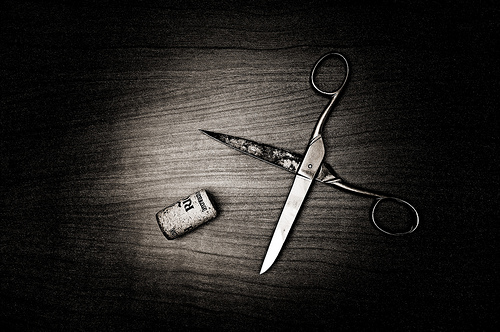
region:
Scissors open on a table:
[192, 53, 421, 270]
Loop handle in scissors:
[372, 193, 419, 238]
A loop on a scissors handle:
[307, 51, 355, 96]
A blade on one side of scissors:
[252, 177, 321, 271]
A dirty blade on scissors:
[197, 126, 297, 176]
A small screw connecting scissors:
[305, 162, 312, 169]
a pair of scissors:
[165, 39, 455, 287]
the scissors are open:
[189, 49, 431, 283]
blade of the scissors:
[239, 160, 334, 307]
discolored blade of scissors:
[195, 118, 290, 180]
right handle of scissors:
[297, 30, 365, 110]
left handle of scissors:
[350, 168, 422, 260]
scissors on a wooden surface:
[23, 11, 474, 322]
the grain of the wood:
[48, 59, 332, 287]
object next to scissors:
[142, 168, 229, 270]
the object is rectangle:
[130, 160, 233, 250]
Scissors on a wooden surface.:
[198, 49, 420, 271]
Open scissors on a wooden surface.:
[198, 48, 419, 275]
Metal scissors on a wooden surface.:
[197, 50, 420, 272]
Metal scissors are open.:
[197, 49, 419, 271]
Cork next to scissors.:
[156, 188, 218, 240]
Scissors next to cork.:
[200, 52, 418, 273]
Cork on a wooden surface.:
[153, 188, 219, 240]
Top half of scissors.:
[260, 51, 350, 274]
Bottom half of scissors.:
[198, 127, 418, 237]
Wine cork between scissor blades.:
[155, 188, 219, 238]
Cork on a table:
[150, 179, 217, 241]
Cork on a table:
[147, 187, 217, 239]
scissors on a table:
[194, 47, 426, 265]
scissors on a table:
[203, 47, 423, 278]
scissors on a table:
[200, 48, 421, 274]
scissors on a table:
[210, 44, 430, 273]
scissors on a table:
[189, 58, 431, 278]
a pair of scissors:
[193, 50, 444, 280]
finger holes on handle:
[308, 38, 424, 248]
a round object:
[155, 171, 225, 250]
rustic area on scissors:
[199, 123, 299, 165]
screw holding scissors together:
[308, 158, 317, 170]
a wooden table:
[3, 9, 489, 327]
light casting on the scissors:
[245, 165, 325, 276]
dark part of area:
[2, 10, 497, 329]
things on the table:
[149, 42, 431, 284]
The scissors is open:
[216, 42, 426, 287]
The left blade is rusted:
[187, 110, 287, 188]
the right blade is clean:
[246, 175, 345, 298]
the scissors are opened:
[198, 51, 420, 273]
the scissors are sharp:
[199, 50, 419, 274]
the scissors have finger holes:
[198, 52, 421, 274]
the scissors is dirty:
[199, 51, 421, 273]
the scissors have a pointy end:
[198, 51, 418, 275]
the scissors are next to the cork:
[156, 51, 419, 275]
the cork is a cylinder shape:
[155, 188, 217, 239]